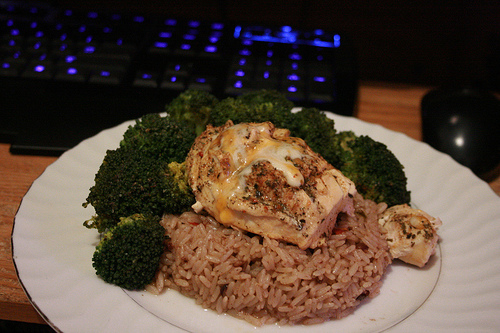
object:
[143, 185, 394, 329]
rice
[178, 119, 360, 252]
meat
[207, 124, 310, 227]
cheese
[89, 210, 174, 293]
broccoli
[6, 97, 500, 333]
plate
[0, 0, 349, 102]
keyboard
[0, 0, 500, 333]
table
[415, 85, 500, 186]
mouse